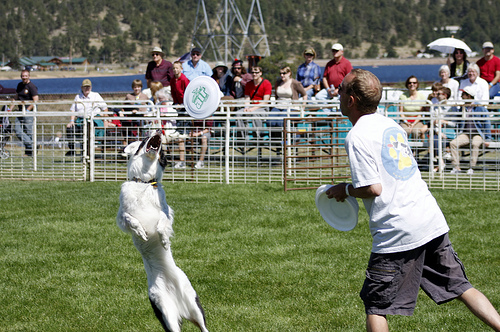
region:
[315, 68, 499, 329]
man playing frisbee in a park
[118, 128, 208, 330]
dog ready to catch a frisbee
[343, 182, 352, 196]
man wearing a white bracelet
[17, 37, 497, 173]
people sitting in the bleachers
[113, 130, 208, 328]
a black and white dog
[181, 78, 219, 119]
a white frisbee with a blue logo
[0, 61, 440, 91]
a blue river in the distance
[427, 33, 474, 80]
woman holding an umbrella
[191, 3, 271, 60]
an electric metal pylon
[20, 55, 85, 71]
a building with a green roof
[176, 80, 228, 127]
white frisbee in air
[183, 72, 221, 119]
white frisbee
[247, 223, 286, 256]
short green grass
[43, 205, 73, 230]
grass has dry patches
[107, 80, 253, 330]
do about to catch a frisbee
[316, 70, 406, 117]
man has on sunglasses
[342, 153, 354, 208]
man wearing a white band around wrist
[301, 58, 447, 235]
person holding frisbees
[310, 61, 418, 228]
person holding 2 frisbees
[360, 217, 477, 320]
gray cargo shorts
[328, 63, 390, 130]
the head of a man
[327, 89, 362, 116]
the ear of a man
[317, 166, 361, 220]
the hand of a man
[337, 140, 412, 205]
the arm of a man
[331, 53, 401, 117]
the hair of a man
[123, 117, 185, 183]
the head of a dog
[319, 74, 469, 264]
a man wearing a shirt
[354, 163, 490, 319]
a man wearing shorts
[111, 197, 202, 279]
the legs of a man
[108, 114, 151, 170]
the ear of a dog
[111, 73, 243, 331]
dog leaping after a frisbee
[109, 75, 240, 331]
dog and frisbee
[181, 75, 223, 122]
white frisbee in the air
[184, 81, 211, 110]
green print on a white frisbee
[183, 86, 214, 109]
white bold light green text on a frisbee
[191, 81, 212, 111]
text on a frisbee reading air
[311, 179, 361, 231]
a couple of white frisbees in a man's hand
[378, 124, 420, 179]
design on the back of a man's shirt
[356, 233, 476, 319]
gray shorts on a man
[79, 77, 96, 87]
tan hat on a man's head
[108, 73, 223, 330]
Dog jumping to catch a frisbee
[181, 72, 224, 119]
Frisbee is in the air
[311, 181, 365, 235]
Man holding a frisbee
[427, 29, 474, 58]
Woman holding a white umbrella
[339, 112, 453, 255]
Man wearing a white shirt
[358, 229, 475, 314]
Man wearing grey pants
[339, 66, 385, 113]
Man has brown hair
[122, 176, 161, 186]
Dog is wearing a collar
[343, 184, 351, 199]
Man is wearing a white band on his wrist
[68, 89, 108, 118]
Man wearing a white shirt